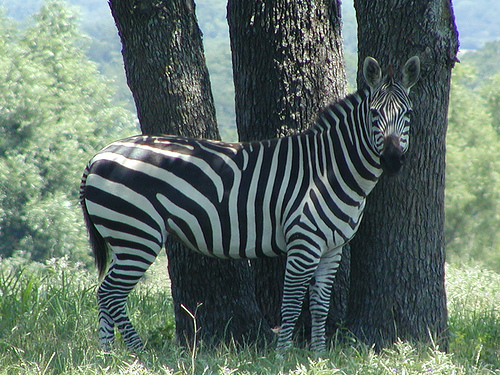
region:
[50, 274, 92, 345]
green grass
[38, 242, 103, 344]
green grass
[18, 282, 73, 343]
green grass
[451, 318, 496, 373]
green grass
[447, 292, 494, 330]
green grass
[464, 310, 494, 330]
green grass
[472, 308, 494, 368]
green grass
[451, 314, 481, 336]
green grass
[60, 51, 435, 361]
zebra standing in the shade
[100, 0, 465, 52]
trunks of three trees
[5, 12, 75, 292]
green leaves on trees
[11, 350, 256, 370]
green grass on ground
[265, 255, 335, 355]
front legs of a zebra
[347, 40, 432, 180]
face of a zebra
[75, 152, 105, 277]
tail of a zebra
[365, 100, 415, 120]
eyes of a zebra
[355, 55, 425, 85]
ears of a zebra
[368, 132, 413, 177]
mouth and nose of a zebra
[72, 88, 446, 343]
zebra standing in front of trees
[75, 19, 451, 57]
three trees in the back of zebra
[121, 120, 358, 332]
black and white stripes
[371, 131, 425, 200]
black nose on a zebra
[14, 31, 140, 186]
tree in the back of the zebra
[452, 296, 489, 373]
green grass field under zebra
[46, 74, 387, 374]
zebra standing in the grass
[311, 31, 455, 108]
ears on the zebra sticking up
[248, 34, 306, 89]
rough bark on the tree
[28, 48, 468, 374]
zebra looking at the camera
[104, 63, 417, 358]
Giraffe in field staring at camera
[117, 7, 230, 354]
Tall brown tree stump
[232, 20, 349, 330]
Tall brown tree stump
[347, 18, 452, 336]
Tall brown tree stump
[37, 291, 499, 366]
Overgrown grass under zebra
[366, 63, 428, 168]
Zebra head staring straight to camera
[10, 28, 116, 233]
Tall green trees in background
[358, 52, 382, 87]
pointed ear of zebra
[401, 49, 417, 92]
pointed ear of zebra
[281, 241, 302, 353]
Right front leg of zebra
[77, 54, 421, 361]
Black and white zebra standing by three trees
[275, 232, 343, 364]
Two front black and white zebra legs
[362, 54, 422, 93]
Two ears on a zebras head.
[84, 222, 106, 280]
Frayed black tail on a zebra.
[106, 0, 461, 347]
Three large trees behind a zebra.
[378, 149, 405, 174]
Nose on a zebra.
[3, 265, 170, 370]
Grass behind a zebras back legs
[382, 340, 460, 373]
Sun shining on the grass in front of a tree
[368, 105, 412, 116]
Two eyes on a zebras face.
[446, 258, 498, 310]
Grass shining to the right of trees.